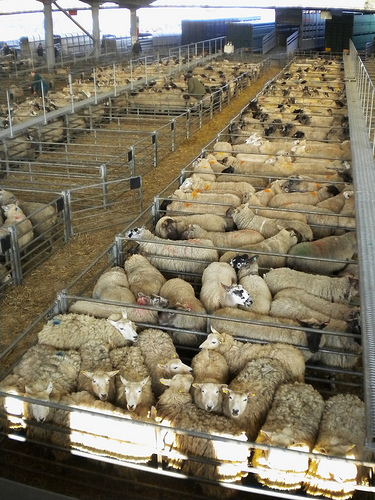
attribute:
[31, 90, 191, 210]
pens — empty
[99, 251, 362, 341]
pen — small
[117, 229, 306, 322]
sheep — hearded, crammed together, uncomfortable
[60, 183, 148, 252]
gate — open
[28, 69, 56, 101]
man — walking, bending over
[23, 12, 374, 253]
building — large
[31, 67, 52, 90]
person — bending over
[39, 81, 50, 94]
coat — green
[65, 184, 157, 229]
fence — open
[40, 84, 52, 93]
jacket — green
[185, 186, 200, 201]
marking — colored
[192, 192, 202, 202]
tags — yellow